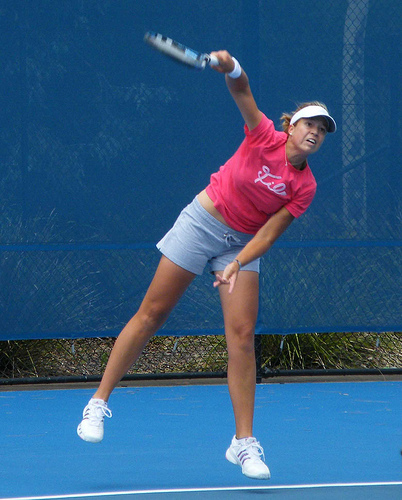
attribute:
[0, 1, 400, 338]
fence — black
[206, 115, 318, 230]
shirt — red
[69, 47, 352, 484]
tennis player — serving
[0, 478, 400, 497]
white line — painted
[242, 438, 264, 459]
laces — tied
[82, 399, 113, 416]
laces — tied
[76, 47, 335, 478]
woman — playing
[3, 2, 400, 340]
divider — blue, mesh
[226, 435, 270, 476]
sneaker — white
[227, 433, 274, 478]
shoe — white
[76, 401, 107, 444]
shoe — white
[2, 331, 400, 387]
fence — black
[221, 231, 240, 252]
string — tightening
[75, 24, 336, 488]
tennis player — jumping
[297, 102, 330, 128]
visor — white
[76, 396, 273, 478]
shoes — white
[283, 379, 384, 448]
floor — blue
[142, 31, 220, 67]
racket — white, blue, black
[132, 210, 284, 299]
shorts — gray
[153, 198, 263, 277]
shorts — blue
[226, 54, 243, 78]
sweatband — white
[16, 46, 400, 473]
court — blue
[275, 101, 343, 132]
visor — white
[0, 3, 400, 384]
fence — chainlink, black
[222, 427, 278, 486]
shoes stripes — blue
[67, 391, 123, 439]
shoes stripes — blue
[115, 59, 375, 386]
woman — playing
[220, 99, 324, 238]
shirt — red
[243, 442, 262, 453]
pins — white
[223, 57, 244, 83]
armband — white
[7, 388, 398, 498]
tennis court — blue